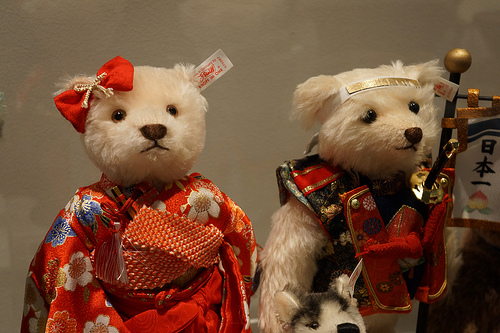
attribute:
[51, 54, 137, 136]
bow — red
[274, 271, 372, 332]
wolf — toy, stuffed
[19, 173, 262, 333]
dress — kimono, red, floral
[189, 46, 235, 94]
tag — white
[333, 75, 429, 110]
headband — gold, white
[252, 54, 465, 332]
bear — dressed up, stuffed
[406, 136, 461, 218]
sword — pretend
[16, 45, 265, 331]
bear — cute, dressed up, white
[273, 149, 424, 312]
vest — black, japanese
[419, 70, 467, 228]
pole — black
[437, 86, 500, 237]
banner — brown, wooden